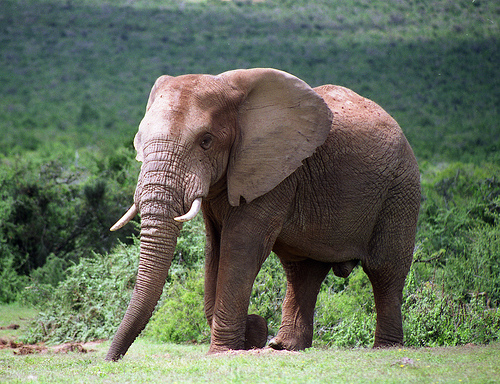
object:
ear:
[223, 66, 334, 206]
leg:
[266, 257, 321, 351]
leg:
[364, 175, 419, 348]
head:
[98, 64, 333, 360]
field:
[0, 291, 497, 381]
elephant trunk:
[103, 190, 189, 362]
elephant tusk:
[174, 198, 203, 222]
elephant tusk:
[110, 203, 138, 231]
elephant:
[102, 67, 421, 364]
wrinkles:
[134, 173, 177, 274]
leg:
[206, 209, 283, 356]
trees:
[0, 136, 495, 340]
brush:
[33, 218, 492, 336]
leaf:
[434, 320, 459, 346]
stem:
[411, 263, 498, 353]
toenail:
[268, 339, 280, 350]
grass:
[0, 163, 499, 378]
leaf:
[360, 338, 372, 349]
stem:
[351, 330, 361, 341]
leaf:
[426, 329, 435, 335]